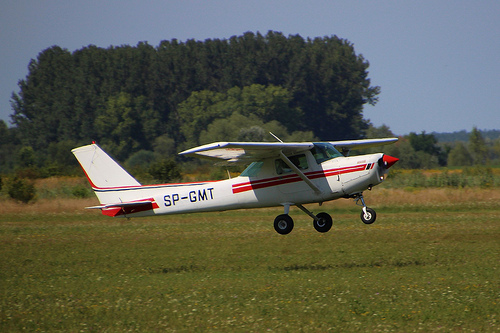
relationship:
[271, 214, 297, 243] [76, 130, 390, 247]
wheel of plane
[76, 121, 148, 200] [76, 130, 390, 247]
tail of plane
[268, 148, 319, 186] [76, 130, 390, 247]
window of plane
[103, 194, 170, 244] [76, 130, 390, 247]
wing of plane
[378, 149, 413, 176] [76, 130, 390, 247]
nose on plane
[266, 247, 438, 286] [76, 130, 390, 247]
shadow of plane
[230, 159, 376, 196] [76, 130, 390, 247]
line on plane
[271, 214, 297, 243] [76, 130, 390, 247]
wheel on plane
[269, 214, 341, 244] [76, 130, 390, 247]
gear on plane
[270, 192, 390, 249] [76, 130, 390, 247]
wheels on plane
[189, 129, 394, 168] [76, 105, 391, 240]
wings on airplane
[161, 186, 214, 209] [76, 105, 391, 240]
letter on airplane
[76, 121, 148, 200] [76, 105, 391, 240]
tail on airplane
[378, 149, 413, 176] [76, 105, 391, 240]
nose on airplane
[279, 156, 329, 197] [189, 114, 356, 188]
struts for wing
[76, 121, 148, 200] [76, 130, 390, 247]
tail on plane